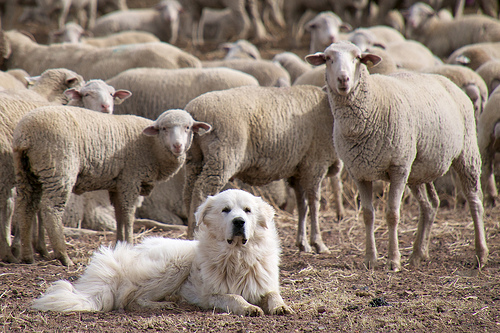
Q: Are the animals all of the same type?
A: No, there are both sheep and dogs.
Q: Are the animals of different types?
A: Yes, they are sheep and dogs.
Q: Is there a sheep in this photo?
A: Yes, there is a sheep.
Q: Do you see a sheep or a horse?
A: Yes, there is a sheep.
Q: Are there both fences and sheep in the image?
A: No, there is a sheep but no fences.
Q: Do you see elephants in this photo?
A: No, there are no elephants.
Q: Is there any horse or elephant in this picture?
A: No, there are no elephants or horses.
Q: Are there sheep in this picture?
A: Yes, there is a sheep.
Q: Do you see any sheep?
A: Yes, there is a sheep.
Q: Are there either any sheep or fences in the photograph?
A: Yes, there is a sheep.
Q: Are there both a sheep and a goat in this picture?
A: No, there is a sheep but no goats.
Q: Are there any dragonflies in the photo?
A: No, there are no dragonflies.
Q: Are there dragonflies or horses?
A: No, there are no dragonflies or horses.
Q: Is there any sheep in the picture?
A: Yes, there is a sheep.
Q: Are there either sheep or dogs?
A: Yes, there is a sheep.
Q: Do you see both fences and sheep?
A: No, there is a sheep but no fences.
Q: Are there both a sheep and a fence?
A: No, there is a sheep but no fences.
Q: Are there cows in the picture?
A: No, there are no cows.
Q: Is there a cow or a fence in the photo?
A: No, there are no cows or fences.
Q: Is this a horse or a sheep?
A: This is a sheep.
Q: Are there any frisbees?
A: No, there are no frisbees.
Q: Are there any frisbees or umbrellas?
A: No, there are no frisbees or umbrellas.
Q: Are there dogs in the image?
A: Yes, there is a dog.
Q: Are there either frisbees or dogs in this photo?
A: Yes, there is a dog.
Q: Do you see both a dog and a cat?
A: No, there is a dog but no cats.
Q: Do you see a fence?
A: No, there are no fences.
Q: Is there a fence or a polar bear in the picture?
A: No, there are no fences or polar bears.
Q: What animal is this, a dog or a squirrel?
A: This is a dog.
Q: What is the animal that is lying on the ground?
A: The animal is a dog.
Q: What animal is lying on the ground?
A: The animal is a dog.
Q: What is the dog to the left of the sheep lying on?
A: The dog is lying on the ground.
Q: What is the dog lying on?
A: The dog is lying on the ground.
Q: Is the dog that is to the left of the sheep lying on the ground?
A: Yes, the dog is lying on the ground.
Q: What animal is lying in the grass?
A: The dog is lying in the grass.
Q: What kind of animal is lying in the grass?
A: The animal is a dog.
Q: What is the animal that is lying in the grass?
A: The animal is a dog.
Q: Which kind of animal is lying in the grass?
A: The animal is a dog.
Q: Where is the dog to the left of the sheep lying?
A: The dog is lying in the grass.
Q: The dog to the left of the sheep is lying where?
A: The dog is lying in the grass.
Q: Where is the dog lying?
A: The dog is lying in the grass.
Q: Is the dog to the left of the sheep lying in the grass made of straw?
A: Yes, the dog is lying in the grass.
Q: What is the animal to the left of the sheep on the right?
A: The animal is a dog.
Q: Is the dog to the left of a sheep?
A: Yes, the dog is to the left of a sheep.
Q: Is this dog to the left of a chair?
A: No, the dog is to the left of a sheep.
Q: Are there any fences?
A: No, there are no fences.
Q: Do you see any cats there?
A: No, there are no cats.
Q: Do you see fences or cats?
A: No, there are no cats or fences.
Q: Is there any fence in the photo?
A: No, there are no fences.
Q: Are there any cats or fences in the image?
A: No, there are no fences or cats.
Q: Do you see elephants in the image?
A: No, there are no elephants.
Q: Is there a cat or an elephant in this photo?
A: No, there are no elephants or cats.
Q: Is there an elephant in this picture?
A: No, there are no elephants.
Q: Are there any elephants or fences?
A: No, there are no elephants or fences.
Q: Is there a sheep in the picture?
A: Yes, there is a sheep.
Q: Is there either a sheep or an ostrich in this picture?
A: Yes, there is a sheep.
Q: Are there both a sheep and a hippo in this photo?
A: No, there is a sheep but no hippoes.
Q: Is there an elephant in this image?
A: No, there are no elephants.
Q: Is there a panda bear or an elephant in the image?
A: No, there are no elephants or pandas.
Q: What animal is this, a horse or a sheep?
A: This is a sheep.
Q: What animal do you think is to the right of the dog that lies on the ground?
A: The animal is a sheep.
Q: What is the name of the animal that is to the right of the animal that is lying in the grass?
A: The animal is a sheep.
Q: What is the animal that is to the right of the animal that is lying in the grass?
A: The animal is a sheep.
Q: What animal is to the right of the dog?
A: The animal is a sheep.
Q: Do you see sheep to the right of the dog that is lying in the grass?
A: Yes, there is a sheep to the right of the dog.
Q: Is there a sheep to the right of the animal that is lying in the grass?
A: Yes, there is a sheep to the right of the dog.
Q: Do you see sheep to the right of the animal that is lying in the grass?
A: Yes, there is a sheep to the right of the dog.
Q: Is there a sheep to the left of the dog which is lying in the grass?
A: No, the sheep is to the right of the dog.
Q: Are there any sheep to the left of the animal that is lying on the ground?
A: No, the sheep is to the right of the dog.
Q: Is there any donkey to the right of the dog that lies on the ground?
A: No, there is a sheep to the right of the dog.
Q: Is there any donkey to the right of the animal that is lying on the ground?
A: No, there is a sheep to the right of the dog.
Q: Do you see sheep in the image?
A: Yes, there is a sheep.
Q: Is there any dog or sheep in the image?
A: Yes, there is a sheep.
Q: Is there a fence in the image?
A: No, there are no fences.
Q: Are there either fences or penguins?
A: No, there are no fences or penguins.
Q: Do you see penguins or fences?
A: No, there are no fences or penguins.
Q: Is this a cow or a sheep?
A: This is a sheep.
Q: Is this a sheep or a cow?
A: This is a sheep.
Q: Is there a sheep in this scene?
A: Yes, there is a sheep.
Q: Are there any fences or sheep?
A: Yes, there is a sheep.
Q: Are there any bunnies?
A: No, there are no bunnies.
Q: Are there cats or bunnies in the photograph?
A: No, there are no bunnies or cats.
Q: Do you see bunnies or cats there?
A: No, there are no bunnies or cats.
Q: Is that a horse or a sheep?
A: That is a sheep.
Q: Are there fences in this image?
A: No, there are no fences.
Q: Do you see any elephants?
A: No, there are no elephants.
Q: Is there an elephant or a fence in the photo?
A: No, there are no elephants or fences.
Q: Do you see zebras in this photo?
A: No, there are no zebras.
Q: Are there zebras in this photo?
A: No, there are no zebras.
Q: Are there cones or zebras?
A: No, there are no zebras or cones.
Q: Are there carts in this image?
A: No, there are no carts.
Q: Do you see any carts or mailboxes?
A: No, there are no carts or mailboxes.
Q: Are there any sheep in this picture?
A: Yes, there is a sheep.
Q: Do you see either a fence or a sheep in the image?
A: Yes, there is a sheep.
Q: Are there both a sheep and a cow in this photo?
A: No, there is a sheep but no cows.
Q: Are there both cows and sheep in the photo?
A: No, there is a sheep but no cows.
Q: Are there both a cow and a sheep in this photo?
A: No, there is a sheep but no cows.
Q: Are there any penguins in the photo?
A: No, there are no penguins.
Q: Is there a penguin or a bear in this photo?
A: No, there are no penguins or bears.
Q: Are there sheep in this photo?
A: Yes, there is a sheep.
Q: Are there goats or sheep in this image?
A: Yes, there is a sheep.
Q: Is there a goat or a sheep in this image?
A: Yes, there is a sheep.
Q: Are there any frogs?
A: No, there are no frogs.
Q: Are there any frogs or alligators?
A: No, there are no frogs or alligators.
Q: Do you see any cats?
A: No, there are no cats.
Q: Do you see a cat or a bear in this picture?
A: No, there are no cats or bears.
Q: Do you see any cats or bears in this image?
A: No, there are no cats or bears.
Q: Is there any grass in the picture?
A: Yes, there is grass.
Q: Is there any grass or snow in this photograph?
A: Yes, there is grass.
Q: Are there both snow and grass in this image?
A: No, there is grass but no snow.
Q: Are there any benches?
A: No, there are no benches.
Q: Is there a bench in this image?
A: No, there are no benches.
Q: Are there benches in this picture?
A: No, there are no benches.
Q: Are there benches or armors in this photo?
A: No, there are no benches or armors.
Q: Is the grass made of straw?
A: Yes, the grass is made of straw.